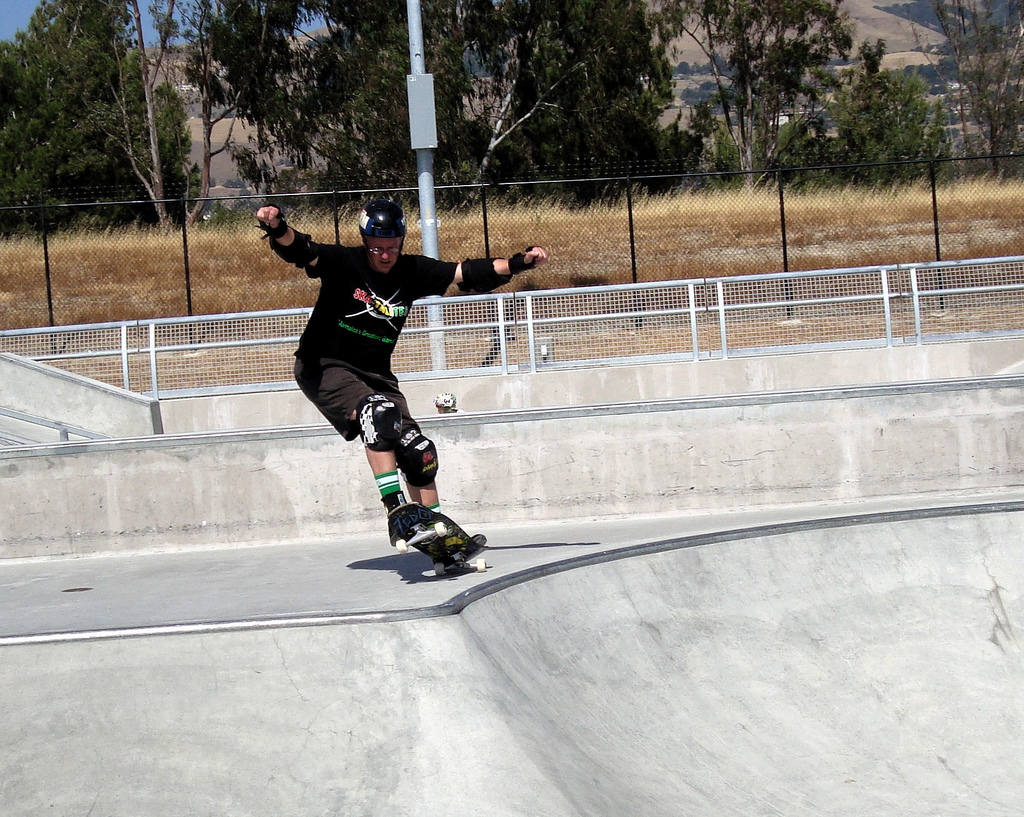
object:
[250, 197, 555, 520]
man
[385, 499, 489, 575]
skateboard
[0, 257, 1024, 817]
skate park